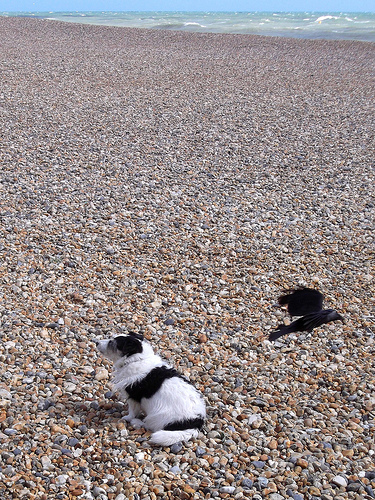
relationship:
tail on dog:
[148, 426, 206, 450] [91, 331, 222, 447]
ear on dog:
[121, 334, 144, 357] [94, 329, 211, 452]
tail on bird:
[271, 323, 289, 346] [267, 283, 347, 344]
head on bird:
[323, 307, 349, 329] [261, 279, 348, 343]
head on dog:
[93, 330, 151, 361] [97, 333, 205, 445]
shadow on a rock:
[62, 401, 126, 429] [103, 403, 112, 409]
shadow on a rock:
[62, 401, 126, 429] [90, 401, 98, 407]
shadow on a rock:
[62, 401, 126, 429] [66, 402, 75, 410]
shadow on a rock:
[62, 401, 126, 429] [88, 413, 96, 419]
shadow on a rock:
[62, 401, 126, 429] [111, 410, 120, 417]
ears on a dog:
[119, 329, 143, 355] [28, 314, 249, 454]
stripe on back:
[126, 365, 175, 402] [120, 362, 201, 425]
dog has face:
[94, 329, 211, 452] [92, 335, 120, 359]